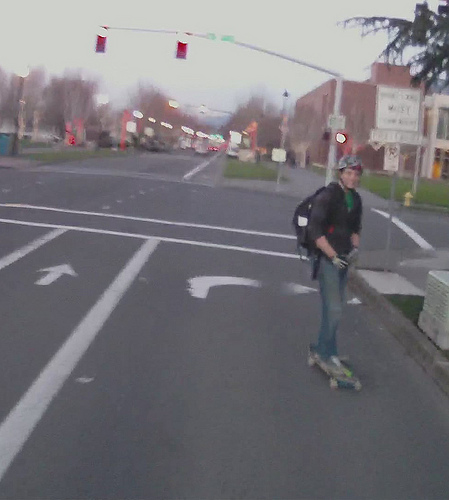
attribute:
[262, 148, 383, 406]
skater — present, here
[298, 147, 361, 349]
man — here, present, standing, skating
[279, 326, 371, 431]
skateboard — under, here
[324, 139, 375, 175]
helmet — worn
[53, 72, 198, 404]
road — marmacked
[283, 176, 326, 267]
bad — here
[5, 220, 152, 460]
strip — white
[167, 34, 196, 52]
light — red, on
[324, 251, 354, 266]
glove — worn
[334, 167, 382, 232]
face — white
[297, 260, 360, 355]
jeans — worn, blue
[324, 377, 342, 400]
wheel — here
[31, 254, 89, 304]
arrow — white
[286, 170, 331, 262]
backpack — here